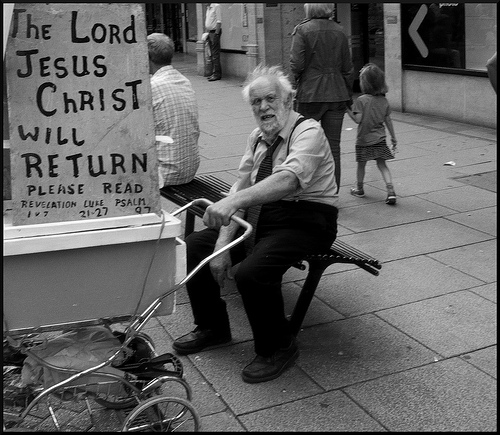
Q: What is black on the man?
A: His pants.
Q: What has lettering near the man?
A: The sign.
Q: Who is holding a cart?
A: The man.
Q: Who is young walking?
A: The girl.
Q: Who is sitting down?
A: The man.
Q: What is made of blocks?
A: The sidewalk.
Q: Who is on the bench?
A: The man.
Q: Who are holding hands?
A: Woman and child.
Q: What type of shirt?
A: White shirt.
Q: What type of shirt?
A: A checkered shirt.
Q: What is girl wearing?
A: A skirt.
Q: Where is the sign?
A: Next to the man.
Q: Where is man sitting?
A: At edge of bench.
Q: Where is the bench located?
A: On sidewalk.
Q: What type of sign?
A: Cardboard sign.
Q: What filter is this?
A: Black and white.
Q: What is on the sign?
A: Words.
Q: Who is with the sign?
A: An old man.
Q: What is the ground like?
A: Large bricks.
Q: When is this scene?
A: Afternoon.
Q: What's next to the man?
A: Walker.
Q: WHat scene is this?
A: Street corner.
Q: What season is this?
A: Spring.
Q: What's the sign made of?
A: Cardboard.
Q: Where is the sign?
A: In front of the man.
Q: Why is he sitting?
A: Resting.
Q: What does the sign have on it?
A: Words.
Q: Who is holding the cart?
A: The man.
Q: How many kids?
A: 1.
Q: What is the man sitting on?
A: Bench.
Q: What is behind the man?
A: Building.